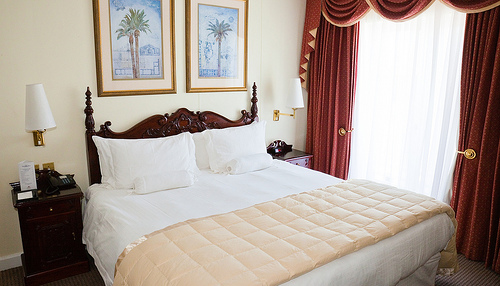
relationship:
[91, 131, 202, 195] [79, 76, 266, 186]
pillow in front of headboard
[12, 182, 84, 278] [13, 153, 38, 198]
nighstand with telephone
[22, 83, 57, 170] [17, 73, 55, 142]
lamp with shad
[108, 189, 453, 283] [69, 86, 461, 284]
quilt folded on foot of bed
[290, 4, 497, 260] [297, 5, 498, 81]
curtains with valance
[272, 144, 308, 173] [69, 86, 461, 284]
nightstand next to bed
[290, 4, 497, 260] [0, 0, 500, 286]
curtains in a bedroom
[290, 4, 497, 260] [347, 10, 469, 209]
curtains with panel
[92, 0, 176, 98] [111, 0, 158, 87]
frame of a palm tree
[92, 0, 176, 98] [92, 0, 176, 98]
frame of frame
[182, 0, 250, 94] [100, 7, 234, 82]
frame of palms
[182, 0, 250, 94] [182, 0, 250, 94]
frame of frame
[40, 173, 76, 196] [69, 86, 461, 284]
nighstand next to a bed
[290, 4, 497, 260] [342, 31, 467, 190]
curtains surrounding window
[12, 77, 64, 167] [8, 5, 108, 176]
lamp attached to a wall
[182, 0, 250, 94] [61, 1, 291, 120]
frame on wall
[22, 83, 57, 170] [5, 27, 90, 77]
lamp on wall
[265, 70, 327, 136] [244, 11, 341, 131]
light on wall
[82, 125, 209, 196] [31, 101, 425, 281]
pillow on bed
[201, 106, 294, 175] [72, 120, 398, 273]
pillow on bed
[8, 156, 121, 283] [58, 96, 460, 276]
desk next to bed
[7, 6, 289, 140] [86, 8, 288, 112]
wall with images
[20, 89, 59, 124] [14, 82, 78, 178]
shade on light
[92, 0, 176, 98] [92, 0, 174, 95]
frame in frame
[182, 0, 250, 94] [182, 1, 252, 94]
frame in frame